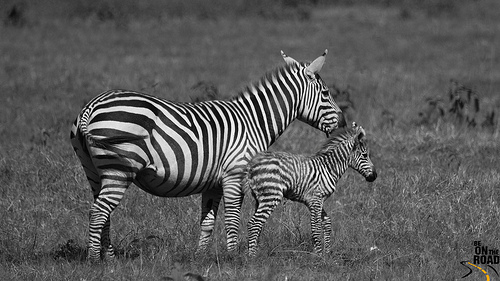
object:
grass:
[20, 13, 497, 53]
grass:
[128, 194, 497, 278]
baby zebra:
[236, 121, 379, 262]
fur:
[318, 124, 359, 161]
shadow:
[40, 236, 140, 266]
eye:
[321, 90, 330, 96]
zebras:
[70, 49, 378, 263]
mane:
[319, 128, 354, 156]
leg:
[86, 166, 124, 261]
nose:
[366, 168, 378, 182]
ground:
[384, 49, 474, 256]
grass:
[0, 0, 499, 281]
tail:
[79, 102, 149, 148]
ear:
[279, 49, 297, 70]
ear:
[308, 48, 329, 74]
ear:
[352, 125, 366, 145]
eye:
[362, 153, 368, 158]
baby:
[238, 121, 378, 260]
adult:
[69, 48, 349, 265]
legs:
[86, 166, 246, 262]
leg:
[221, 164, 244, 261]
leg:
[243, 182, 282, 261]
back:
[114, 94, 254, 138]